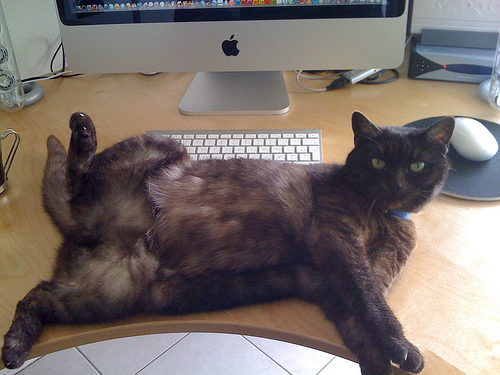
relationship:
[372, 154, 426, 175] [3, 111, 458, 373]
eyes of cat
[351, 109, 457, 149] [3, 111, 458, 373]
ears of cat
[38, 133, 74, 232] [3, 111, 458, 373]
tail of cat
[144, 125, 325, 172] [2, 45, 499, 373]
keybaord on desk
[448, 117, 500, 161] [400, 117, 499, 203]
mouse on pad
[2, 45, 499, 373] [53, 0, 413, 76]
desk has computer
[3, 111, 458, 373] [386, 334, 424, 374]
cat of paw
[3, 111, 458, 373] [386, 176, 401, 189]
cat has nose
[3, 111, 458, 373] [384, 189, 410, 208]
cat has mouth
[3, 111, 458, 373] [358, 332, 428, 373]
cat has paws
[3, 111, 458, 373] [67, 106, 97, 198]
cat has foot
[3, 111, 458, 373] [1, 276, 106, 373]
cat has leg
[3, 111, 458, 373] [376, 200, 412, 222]
cat wearing collar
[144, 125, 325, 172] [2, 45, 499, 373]
keybaord at desk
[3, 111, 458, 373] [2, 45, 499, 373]
cat at desk